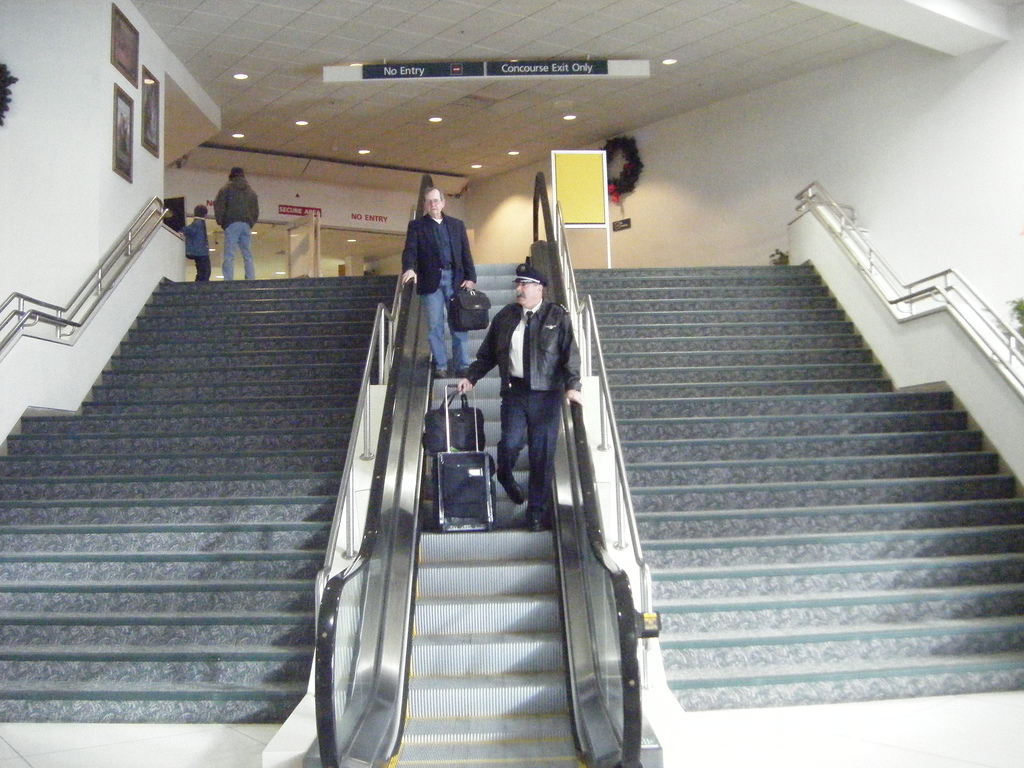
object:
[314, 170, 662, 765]
escalator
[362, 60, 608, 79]
sign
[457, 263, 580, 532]
man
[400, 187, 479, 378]
person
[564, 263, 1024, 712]
stairs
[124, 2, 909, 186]
ceiling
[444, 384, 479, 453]
handle